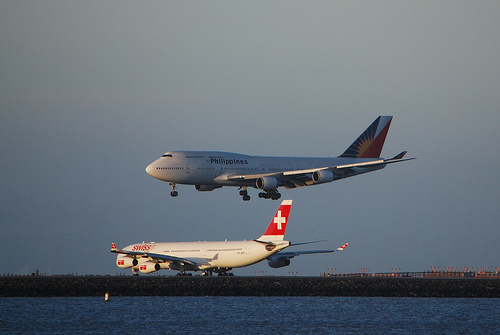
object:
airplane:
[143, 115, 419, 202]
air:
[0, 1, 498, 312]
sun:
[341, 128, 377, 160]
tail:
[338, 115, 393, 159]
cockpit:
[156, 151, 179, 162]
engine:
[252, 175, 278, 191]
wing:
[213, 151, 429, 190]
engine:
[192, 181, 219, 192]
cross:
[273, 211, 286, 232]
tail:
[257, 199, 293, 240]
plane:
[109, 199, 349, 278]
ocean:
[0, 297, 499, 335]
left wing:
[109, 242, 200, 269]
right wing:
[279, 240, 349, 255]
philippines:
[208, 156, 253, 166]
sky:
[0, 0, 499, 276]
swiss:
[131, 243, 151, 253]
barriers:
[253, 263, 499, 278]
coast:
[0, 275, 499, 298]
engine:
[136, 261, 160, 274]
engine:
[265, 257, 290, 268]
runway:
[0, 272, 497, 282]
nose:
[141, 159, 168, 179]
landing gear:
[168, 183, 282, 201]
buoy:
[101, 291, 111, 302]